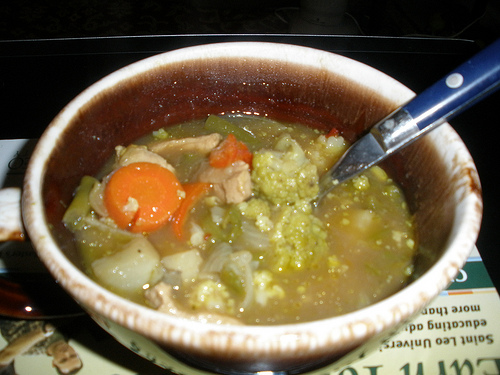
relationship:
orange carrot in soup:
[101, 160, 186, 235] [65, 108, 411, 328]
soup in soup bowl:
[65, 108, 411, 328] [21, 33, 485, 372]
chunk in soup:
[214, 161, 254, 203] [125, 117, 368, 295]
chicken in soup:
[208, 161, 253, 201] [125, 117, 368, 295]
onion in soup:
[202, 240, 234, 274] [65, 108, 411, 328]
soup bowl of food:
[21, 33, 485, 372] [61, 107, 418, 326]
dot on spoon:
[420, 63, 498, 117] [353, 51, 471, 152]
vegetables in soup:
[106, 148, 393, 295] [28, 64, 456, 321]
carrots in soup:
[88, 137, 283, 224] [65, 108, 411, 328]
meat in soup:
[199, 160, 254, 204] [65, 108, 411, 328]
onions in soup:
[205, 212, 267, 301] [65, 108, 411, 328]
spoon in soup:
[323, 49, 497, 178] [65, 108, 411, 328]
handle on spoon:
[400, 50, 499, 132] [341, 75, 464, 160]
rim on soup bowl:
[22, 41, 481, 358] [21, 33, 485, 372]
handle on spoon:
[409, 40, 498, 135] [306, 42, 498, 206]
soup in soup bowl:
[125, 117, 368, 295] [21, 33, 485, 372]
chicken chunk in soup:
[193, 147, 292, 217] [67, 97, 469, 327]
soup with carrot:
[65, 108, 411, 328] [102, 162, 183, 234]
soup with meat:
[65, 108, 411, 328] [199, 160, 254, 204]